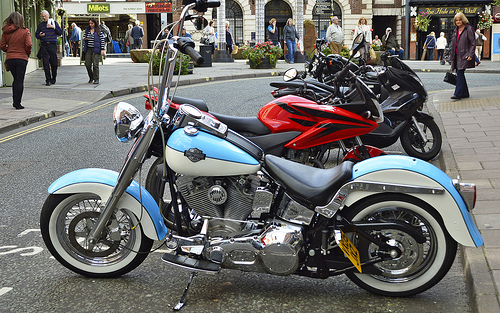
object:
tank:
[256, 95, 379, 150]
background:
[0, 1, 499, 113]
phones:
[40, 31, 47, 34]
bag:
[442, 71, 458, 85]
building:
[0, 0, 500, 64]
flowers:
[243, 40, 275, 55]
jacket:
[449, 24, 476, 70]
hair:
[453, 10, 469, 26]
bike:
[142, 31, 442, 161]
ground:
[0, 57, 500, 313]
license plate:
[334, 228, 362, 274]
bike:
[37, 0, 482, 298]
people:
[0, 11, 32, 110]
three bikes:
[38, 0, 483, 297]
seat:
[263, 153, 354, 206]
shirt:
[78, 28, 110, 53]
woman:
[444, 11, 477, 100]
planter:
[246, 53, 277, 68]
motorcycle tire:
[38, 193, 155, 279]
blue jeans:
[284, 39, 298, 62]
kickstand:
[170, 267, 196, 311]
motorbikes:
[38, 0, 483, 298]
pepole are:
[37, 6, 62, 87]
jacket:
[0, 22, 33, 61]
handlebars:
[172, 1, 222, 65]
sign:
[87, 3, 111, 13]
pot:
[247, 46, 277, 69]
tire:
[327, 191, 457, 298]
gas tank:
[207, 185, 228, 206]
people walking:
[82, 17, 107, 84]